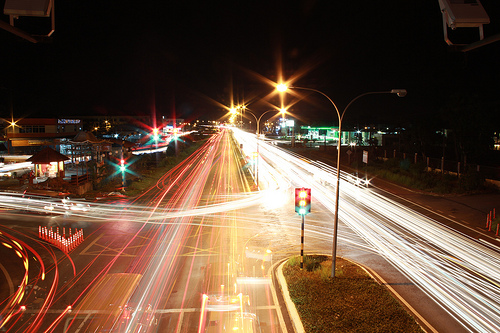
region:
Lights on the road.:
[192, 46, 408, 177]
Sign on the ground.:
[265, 152, 372, 329]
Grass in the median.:
[248, 170, 440, 315]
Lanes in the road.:
[106, 125, 447, 250]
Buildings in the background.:
[34, 98, 176, 201]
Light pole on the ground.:
[254, 35, 439, 287]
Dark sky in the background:
[131, 15, 477, 187]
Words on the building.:
[56, 121, 123, 145]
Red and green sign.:
[261, 161, 388, 276]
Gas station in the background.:
[281, 101, 450, 219]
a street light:
[232, 147, 347, 325]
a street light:
[285, 164, 360, 315]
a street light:
[267, 171, 321, 319]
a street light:
[281, 210, 341, 317]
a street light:
[258, 138, 306, 293]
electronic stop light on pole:
[295, 186, 311, 256]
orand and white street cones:
[38, 222, 85, 252]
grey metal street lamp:
[273, 73, 417, 285]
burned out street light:
[393, 84, 410, 99]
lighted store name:
[57, 118, 82, 126]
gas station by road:
[301, 121, 378, 142]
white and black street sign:
[360, 149, 370, 163]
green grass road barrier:
[276, 255, 431, 332]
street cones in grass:
[484, 207, 499, 238]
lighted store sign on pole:
[281, 116, 296, 128]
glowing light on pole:
[260, 73, 307, 101]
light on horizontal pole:
[375, 81, 420, 103]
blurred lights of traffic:
[357, 190, 447, 279]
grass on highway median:
[297, 278, 368, 319]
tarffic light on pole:
[289, 183, 322, 231]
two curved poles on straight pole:
[317, 86, 369, 150]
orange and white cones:
[30, 222, 92, 253]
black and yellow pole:
[290, 222, 314, 277]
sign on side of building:
[47, 114, 86, 132]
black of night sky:
[116, 26, 191, 79]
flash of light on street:
[253, 69, 305, 110]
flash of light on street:
[219, 92, 240, 132]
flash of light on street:
[268, 101, 290, 125]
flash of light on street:
[112, 165, 134, 179]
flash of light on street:
[117, 155, 128, 167]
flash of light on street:
[151, 135, 163, 144]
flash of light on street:
[151, 122, 162, 134]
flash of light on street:
[167, 125, 179, 132]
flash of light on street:
[169, 132, 185, 148]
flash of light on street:
[243, 103, 250, 113]